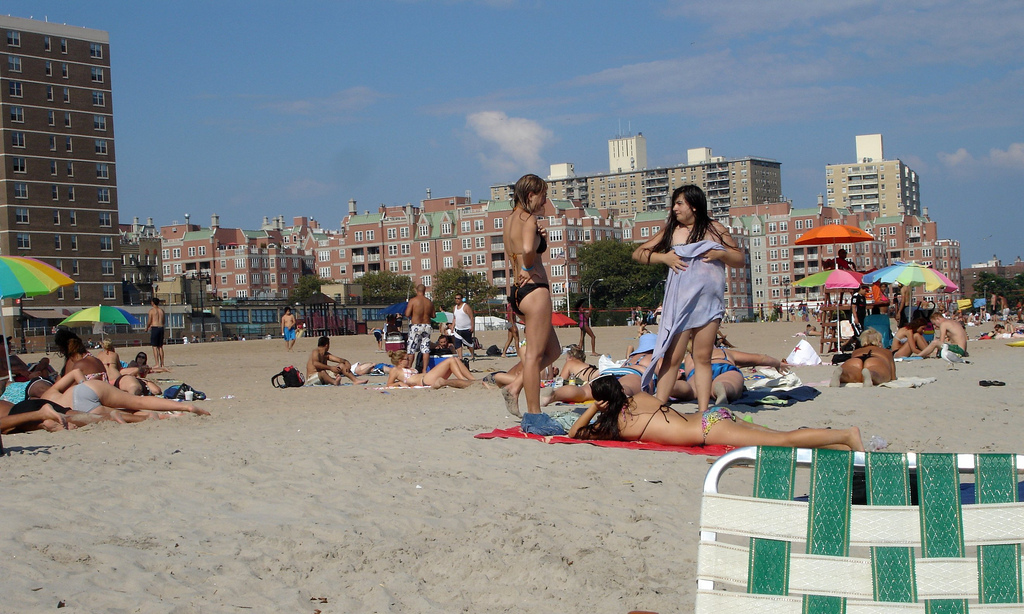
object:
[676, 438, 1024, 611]
chair back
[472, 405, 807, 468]
beach towel